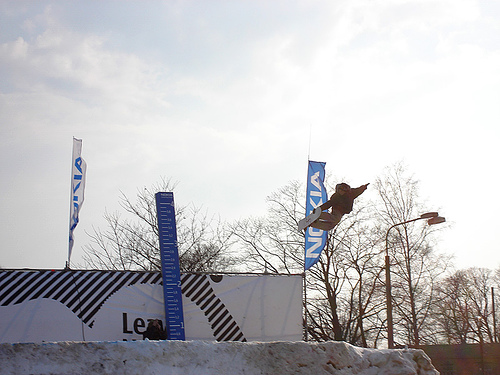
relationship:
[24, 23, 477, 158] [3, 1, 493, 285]
clouds within sky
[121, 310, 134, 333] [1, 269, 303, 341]
letter printed on banner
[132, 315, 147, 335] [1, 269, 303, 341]
letter e printed on banner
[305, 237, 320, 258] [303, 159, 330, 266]
white n printed on blue fabric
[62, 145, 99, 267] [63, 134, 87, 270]
nokia printed on banner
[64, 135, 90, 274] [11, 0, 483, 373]
banner in wind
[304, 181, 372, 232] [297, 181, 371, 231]
man doing a trick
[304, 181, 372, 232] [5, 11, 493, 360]
man in air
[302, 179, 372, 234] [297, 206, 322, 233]
man riding board